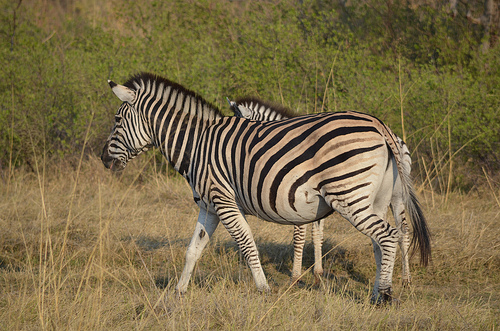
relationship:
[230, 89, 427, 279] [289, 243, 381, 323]
baby zebra walking in grass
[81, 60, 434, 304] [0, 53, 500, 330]
zebra walking in grass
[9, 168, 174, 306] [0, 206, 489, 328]
grass in foreground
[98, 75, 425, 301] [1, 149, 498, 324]
animal in field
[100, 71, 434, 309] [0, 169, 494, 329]
animal in field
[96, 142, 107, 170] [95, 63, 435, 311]
black nose on body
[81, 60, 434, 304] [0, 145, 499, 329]
zebra in grass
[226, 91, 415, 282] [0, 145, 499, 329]
baby zebra in grass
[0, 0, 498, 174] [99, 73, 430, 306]
bushes behind zebras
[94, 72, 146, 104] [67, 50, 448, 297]
ear of zebra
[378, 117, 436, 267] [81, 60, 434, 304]
tail of zebra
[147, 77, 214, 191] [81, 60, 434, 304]
neck of zebra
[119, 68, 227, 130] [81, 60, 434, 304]
mane of zebra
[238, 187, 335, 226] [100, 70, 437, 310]
stomach of zebra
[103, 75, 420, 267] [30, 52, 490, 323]
zebra in field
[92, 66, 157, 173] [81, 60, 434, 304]
head of zebra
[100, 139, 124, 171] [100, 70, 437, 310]
nose on zebra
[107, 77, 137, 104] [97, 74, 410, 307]
ear of zebra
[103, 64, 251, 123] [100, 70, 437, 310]
mohawk of zebra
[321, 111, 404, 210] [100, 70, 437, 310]
ass of zebra